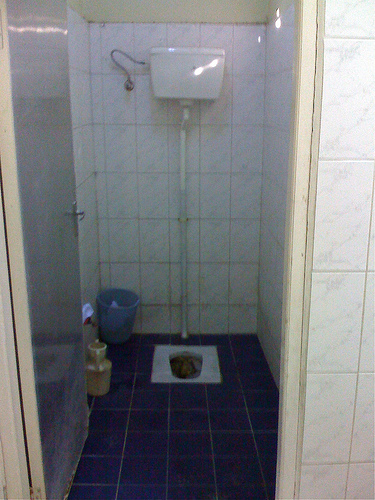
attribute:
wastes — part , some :
[170, 352, 197, 377]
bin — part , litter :
[91, 271, 146, 356]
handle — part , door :
[75, 208, 86, 222]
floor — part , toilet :
[127, 389, 254, 482]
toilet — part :
[149, 340, 222, 383]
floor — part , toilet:
[67, 332, 280, 498]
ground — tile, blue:
[65, 335, 278, 499]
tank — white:
[148, 43, 228, 103]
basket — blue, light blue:
[95, 286, 140, 346]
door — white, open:
[1, 0, 90, 499]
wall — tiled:
[87, 21, 260, 333]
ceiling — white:
[69, 1, 274, 24]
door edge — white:
[1, 201, 34, 500]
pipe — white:
[178, 103, 194, 341]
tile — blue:
[214, 456, 263, 486]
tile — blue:
[228, 332, 260, 348]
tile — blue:
[133, 344, 156, 375]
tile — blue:
[126, 408, 171, 433]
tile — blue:
[74, 454, 124, 488]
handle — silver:
[76, 208, 88, 222]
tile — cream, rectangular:
[101, 22, 136, 76]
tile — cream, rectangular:
[233, 25, 265, 78]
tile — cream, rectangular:
[100, 71, 136, 124]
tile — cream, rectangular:
[231, 75, 268, 127]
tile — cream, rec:
[134, 123, 170, 176]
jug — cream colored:
[81, 336, 113, 396]